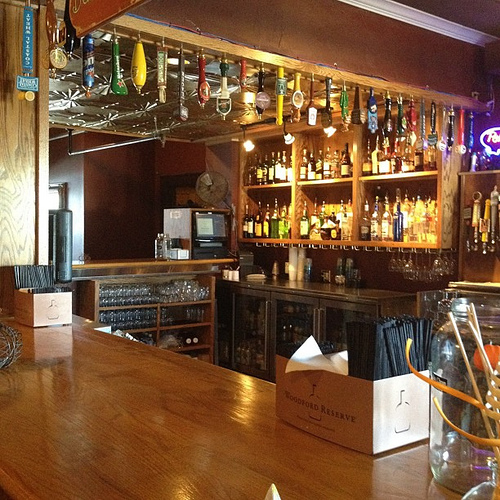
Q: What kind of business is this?
A: Bar.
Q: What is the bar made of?
A: Wood.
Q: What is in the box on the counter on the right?
A: Stirrers.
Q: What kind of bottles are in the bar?
A: Alcohol.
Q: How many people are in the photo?
A: None.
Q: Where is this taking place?
A: At a bar.